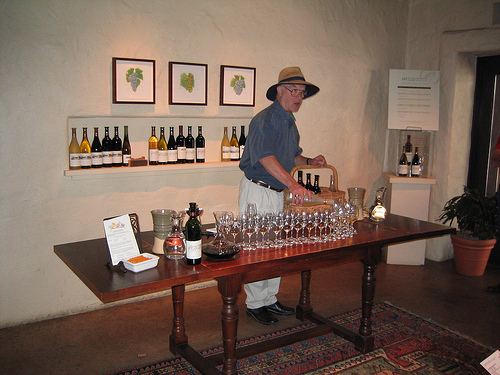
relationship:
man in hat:
[238, 66, 326, 327] [262, 66, 315, 96]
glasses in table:
[214, 186, 374, 247] [240, 248, 344, 266]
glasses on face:
[282, 83, 307, 101] [284, 88, 306, 113]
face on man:
[284, 88, 306, 113] [242, 64, 312, 330]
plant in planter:
[436, 176, 498, 276] [451, 230, 497, 276]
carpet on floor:
[136, 290, 499, 373] [2, 258, 498, 373]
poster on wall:
[111, 59, 157, 107] [212, 31, 376, 81]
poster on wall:
[166, 60, 206, 103] [212, 31, 376, 81]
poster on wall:
[221, 65, 256, 107] [212, 31, 376, 81]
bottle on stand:
[397, 132, 414, 161] [379, 64, 441, 269]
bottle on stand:
[409, 154, 421, 175] [379, 64, 441, 269]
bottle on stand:
[392, 151, 409, 179] [379, 64, 441, 269]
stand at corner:
[379, 64, 441, 269] [397, 10, 419, 71]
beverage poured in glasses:
[77, 124, 92, 168] [209, 199, 360, 251]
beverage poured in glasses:
[69, 127, 81, 169] [209, 199, 360, 251]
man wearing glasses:
[238, 66, 326, 326] [280, 84, 307, 100]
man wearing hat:
[238, 66, 326, 326] [267, 67, 315, 96]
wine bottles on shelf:
[66, 123, 246, 170] [66, 158, 240, 175]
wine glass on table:
[246, 219, 266, 257] [57, 166, 499, 293]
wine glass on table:
[289, 209, 308, 236] [57, 166, 499, 293]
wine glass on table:
[336, 204, 354, 236] [57, 166, 499, 293]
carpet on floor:
[115, 298, 500, 375] [2, 258, 498, 373]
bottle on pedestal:
[411, 145, 421, 177] [385, 172, 437, 266]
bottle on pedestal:
[403, 134, 413, 166] [385, 172, 437, 266]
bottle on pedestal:
[398, 150, 408, 177] [385, 172, 437, 266]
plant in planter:
[435, 183, 500, 242] [440, 219, 495, 279]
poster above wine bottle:
[382, 65, 440, 129] [397, 145, 408, 180]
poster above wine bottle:
[382, 65, 440, 129] [411, 145, 420, 175]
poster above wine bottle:
[382, 65, 440, 129] [404, 133, 412, 160]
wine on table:
[170, 197, 213, 264] [108, 277, 268, 322]